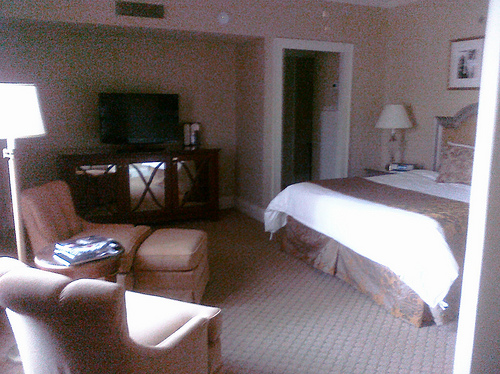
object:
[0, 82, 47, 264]
floor lamp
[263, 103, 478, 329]
bed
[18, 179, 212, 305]
chair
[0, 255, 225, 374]
chair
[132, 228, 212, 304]
ottoman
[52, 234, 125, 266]
stack of magazines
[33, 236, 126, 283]
end table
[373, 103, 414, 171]
lamp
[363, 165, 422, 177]
table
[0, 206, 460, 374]
floor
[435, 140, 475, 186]
pillow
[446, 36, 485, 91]
picture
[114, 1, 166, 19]
vent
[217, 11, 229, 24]
fire alarm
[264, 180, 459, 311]
blanket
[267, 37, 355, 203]
doorway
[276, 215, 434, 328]
bed skirt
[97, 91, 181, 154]
television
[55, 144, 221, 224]
stand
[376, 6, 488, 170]
wall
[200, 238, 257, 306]
shadow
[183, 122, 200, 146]
books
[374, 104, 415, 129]
lamp shade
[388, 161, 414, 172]
book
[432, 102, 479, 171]
headboard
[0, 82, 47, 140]
lamp shade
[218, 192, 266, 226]
floor trim